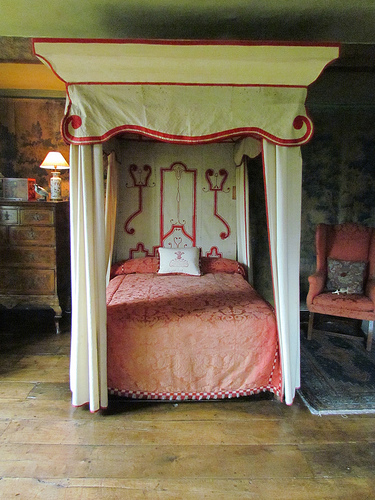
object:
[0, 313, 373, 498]
floor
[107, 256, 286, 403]
blanket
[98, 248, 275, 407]
bed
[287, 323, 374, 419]
rug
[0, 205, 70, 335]
dresser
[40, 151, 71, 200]
lamp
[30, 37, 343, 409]
canopy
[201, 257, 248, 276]
pillow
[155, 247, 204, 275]
pillow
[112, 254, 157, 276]
pillow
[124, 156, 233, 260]
decoration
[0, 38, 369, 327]
wall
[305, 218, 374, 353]
chair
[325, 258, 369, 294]
pillow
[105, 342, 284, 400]
fringe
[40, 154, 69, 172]
shade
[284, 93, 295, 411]
post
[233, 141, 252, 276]
post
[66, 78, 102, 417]
post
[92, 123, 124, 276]
post